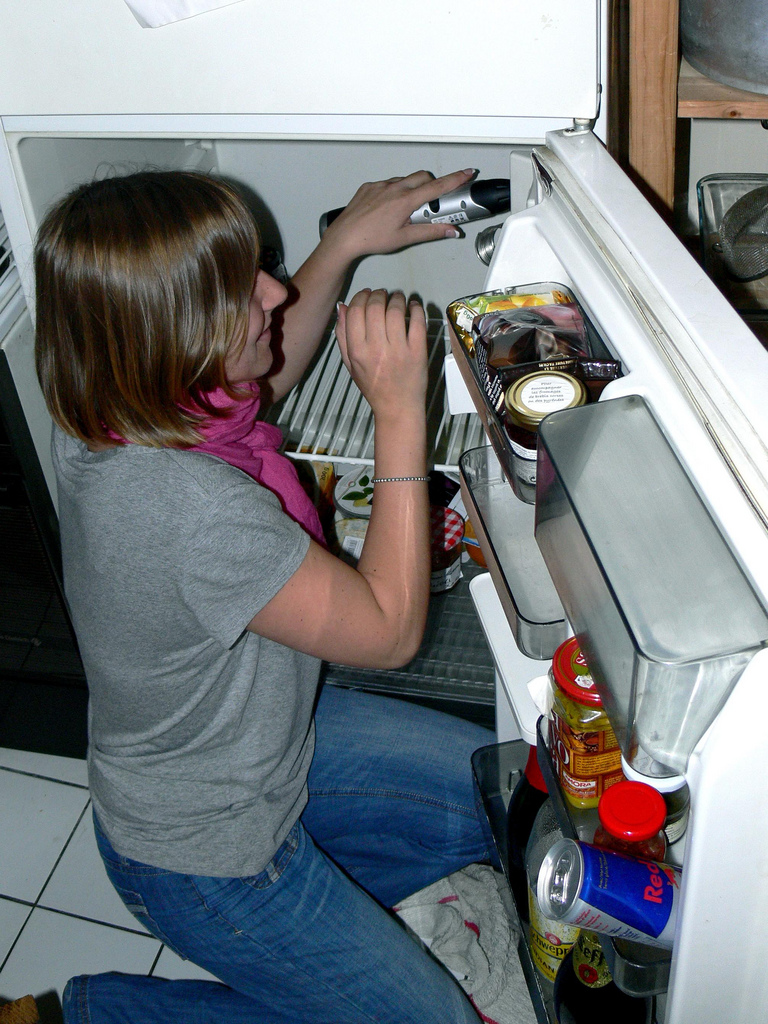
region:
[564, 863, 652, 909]
A can sticking out on the side of a fridge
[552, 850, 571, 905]
The aluminium top of a can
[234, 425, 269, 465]
A pink scarf around a woman's neck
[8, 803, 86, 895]
White tiles on the floor behind the woman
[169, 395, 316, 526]
Pink scarf around woman's neck.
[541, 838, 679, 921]
Can of red bull in fridge.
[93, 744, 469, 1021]
Woman wearing blue jeans.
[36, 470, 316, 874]
Woman wearing gray shirt.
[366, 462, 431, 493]
Silver bracelet around woman's wrist.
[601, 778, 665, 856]
Round red lid on container.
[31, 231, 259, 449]
Woman has brown hair.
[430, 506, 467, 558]
Red and white lid on container.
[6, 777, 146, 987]
White tiles on floor in room.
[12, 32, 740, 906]
Fridge is white in color.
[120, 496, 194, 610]
the girls shirt is light gray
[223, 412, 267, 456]
the girls scarf is pink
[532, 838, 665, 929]
the can is leaning sideways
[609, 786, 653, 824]
the lid on the jar is red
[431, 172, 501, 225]
the girl is using a tool in the fridge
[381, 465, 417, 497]
the girl is wearing a bracelet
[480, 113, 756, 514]
the door on the fridge is open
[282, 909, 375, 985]
the girls jeans are blue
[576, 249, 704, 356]
The fridge is white.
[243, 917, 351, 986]
Her jeans are blue.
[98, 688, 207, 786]
Her shirt is gray.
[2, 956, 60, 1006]
Her shoes are brown.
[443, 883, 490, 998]
The towel is there.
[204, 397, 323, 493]
She has a pink scarf.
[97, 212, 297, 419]
girl has brown hair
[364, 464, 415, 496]
girl is wearing bracelet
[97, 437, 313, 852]
girl has grey shirt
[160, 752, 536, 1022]
girl has blue pants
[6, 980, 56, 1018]
girl has brown shoes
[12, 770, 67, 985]
white tile on floor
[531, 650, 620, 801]
red lid on jar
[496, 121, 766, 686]
white door on fridge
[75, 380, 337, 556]
A pink woman's scarf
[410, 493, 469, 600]
A jar of Smucker's jam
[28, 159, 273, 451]
Short sandy brown hair on a woman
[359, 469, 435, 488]
A bracelet on a woman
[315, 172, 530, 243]
A small motorized hand tool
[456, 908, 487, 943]
Red spot on a piece of towel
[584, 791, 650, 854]
A jar of food.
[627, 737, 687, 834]
A jar of food.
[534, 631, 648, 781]
A jar of food.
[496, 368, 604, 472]
A jar of food.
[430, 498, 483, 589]
A jar of food.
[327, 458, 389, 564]
A jar of food.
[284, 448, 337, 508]
A jar of food.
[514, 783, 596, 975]
A bottle for holding liquid.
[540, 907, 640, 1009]
A bottle for holding liquid.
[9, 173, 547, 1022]
woman wearing gray shirt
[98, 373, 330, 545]
pink scarf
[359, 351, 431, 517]
silver bracelet on wrist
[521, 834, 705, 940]
blue and silver redbull can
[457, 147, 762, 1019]
open fridge door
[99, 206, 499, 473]
empty fridge shelf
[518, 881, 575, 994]
white and yellow soda can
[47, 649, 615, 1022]
woman wearing blue jeans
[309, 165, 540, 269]
woman holding silver cylinder